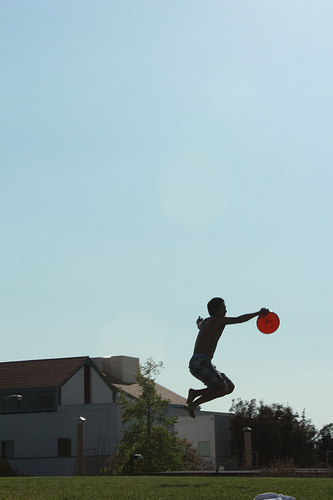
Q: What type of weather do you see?
A: It is clear.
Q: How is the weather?
A: It is clear.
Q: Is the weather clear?
A: Yes, it is clear.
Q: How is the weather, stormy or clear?
A: It is clear.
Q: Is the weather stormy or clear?
A: It is clear.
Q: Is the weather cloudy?
A: No, it is clear.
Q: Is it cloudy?
A: No, it is clear.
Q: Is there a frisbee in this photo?
A: Yes, there is a frisbee.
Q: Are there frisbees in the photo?
A: Yes, there is a frisbee.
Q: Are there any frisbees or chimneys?
A: Yes, there is a frisbee.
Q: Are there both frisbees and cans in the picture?
A: No, there is a frisbee but no cans.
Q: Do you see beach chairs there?
A: No, there are no beach chairs.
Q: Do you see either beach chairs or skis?
A: No, there are no beach chairs or skis.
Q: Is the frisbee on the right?
A: Yes, the frisbee is on the right of the image.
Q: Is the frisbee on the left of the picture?
A: No, the frisbee is on the right of the image.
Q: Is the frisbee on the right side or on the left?
A: The frisbee is on the right of the image.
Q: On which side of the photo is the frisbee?
A: The frisbee is on the right of the image.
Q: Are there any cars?
A: No, there are no cars.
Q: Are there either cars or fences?
A: No, there are no cars or fences.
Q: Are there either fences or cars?
A: No, there are no cars or fences.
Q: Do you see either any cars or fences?
A: No, there are no cars or fences.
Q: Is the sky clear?
A: Yes, the sky is clear.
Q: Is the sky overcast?
A: No, the sky is clear.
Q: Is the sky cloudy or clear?
A: The sky is clear.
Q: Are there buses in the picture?
A: No, there are no buses.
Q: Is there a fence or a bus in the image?
A: No, there are no buses or fences.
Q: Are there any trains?
A: No, there are no trains.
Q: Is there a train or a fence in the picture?
A: No, there are no trains or fences.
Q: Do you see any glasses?
A: No, there are no glasses.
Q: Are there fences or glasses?
A: No, there are no glasses or fences.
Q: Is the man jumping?
A: Yes, the man is jumping.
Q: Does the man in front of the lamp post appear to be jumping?
A: Yes, the man is jumping.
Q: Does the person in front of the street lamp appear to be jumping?
A: Yes, the man is jumping.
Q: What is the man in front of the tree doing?
A: The man is jumping.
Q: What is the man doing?
A: The man is jumping.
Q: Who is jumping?
A: The man is jumping.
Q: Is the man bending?
A: No, the man is jumping.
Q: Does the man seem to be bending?
A: No, the man is jumping.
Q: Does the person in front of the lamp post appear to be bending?
A: No, the man is jumping.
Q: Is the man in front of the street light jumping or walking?
A: The man is jumping.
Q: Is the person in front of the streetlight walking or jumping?
A: The man is jumping.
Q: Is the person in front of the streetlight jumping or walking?
A: The man is jumping.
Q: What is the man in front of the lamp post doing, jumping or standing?
A: The man is jumping.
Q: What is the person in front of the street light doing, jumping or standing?
A: The man is jumping.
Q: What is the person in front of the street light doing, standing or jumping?
A: The man is jumping.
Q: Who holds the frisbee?
A: The man holds the frisbee.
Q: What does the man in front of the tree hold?
A: The man holds the frisbee.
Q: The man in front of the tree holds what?
A: The man holds the frisbee.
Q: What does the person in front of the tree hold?
A: The man holds the frisbee.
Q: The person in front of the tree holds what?
A: The man holds the frisbee.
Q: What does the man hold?
A: The man holds the frisbee.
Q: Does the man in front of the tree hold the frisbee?
A: Yes, the man holds the frisbee.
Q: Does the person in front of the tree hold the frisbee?
A: Yes, the man holds the frisbee.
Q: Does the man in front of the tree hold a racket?
A: No, the man holds the frisbee.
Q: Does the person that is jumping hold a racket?
A: No, the man holds the frisbee.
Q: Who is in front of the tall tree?
A: The man is in front of the tree.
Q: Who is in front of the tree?
A: The man is in front of the tree.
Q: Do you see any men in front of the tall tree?
A: Yes, there is a man in front of the tree.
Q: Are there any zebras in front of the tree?
A: No, there is a man in front of the tree.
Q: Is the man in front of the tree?
A: Yes, the man is in front of the tree.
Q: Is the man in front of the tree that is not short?
A: Yes, the man is in front of the tree.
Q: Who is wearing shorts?
A: The man is wearing shorts.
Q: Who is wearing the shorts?
A: The man is wearing shorts.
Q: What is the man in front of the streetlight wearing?
A: The man is wearing shorts.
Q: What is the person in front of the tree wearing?
A: The man is wearing shorts.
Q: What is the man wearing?
A: The man is wearing shorts.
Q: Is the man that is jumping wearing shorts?
A: Yes, the man is wearing shorts.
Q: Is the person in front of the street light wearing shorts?
A: Yes, the man is wearing shorts.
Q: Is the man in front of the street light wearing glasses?
A: No, the man is wearing shorts.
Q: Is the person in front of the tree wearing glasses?
A: No, the man is wearing shorts.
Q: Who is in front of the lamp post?
A: The man is in front of the lamp post.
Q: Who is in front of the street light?
A: The man is in front of the lamp post.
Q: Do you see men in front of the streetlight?
A: Yes, there is a man in front of the streetlight.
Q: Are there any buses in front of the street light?
A: No, there is a man in front of the street light.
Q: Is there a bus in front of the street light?
A: No, there is a man in front of the street light.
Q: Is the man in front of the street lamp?
A: Yes, the man is in front of the street lamp.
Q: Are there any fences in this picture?
A: No, there are no fences.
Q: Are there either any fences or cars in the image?
A: No, there are no fences or cars.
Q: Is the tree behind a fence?
A: No, the tree is behind the man.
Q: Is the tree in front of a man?
A: No, the tree is behind a man.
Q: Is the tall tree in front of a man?
A: No, the tree is behind a man.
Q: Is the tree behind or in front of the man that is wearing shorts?
A: The tree is behind the man.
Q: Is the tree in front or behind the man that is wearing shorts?
A: The tree is behind the man.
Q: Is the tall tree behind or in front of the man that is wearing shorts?
A: The tree is behind the man.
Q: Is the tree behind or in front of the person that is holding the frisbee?
A: The tree is behind the man.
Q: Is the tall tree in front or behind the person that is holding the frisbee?
A: The tree is behind the man.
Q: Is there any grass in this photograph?
A: Yes, there is grass.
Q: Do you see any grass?
A: Yes, there is grass.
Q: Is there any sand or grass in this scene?
A: Yes, there is grass.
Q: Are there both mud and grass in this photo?
A: No, there is grass but no mud.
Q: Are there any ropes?
A: No, there are no ropes.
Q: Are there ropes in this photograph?
A: No, there are no ropes.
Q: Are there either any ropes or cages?
A: No, there are no ropes or cages.